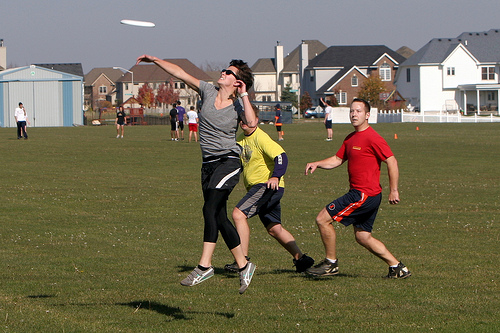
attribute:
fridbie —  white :
[118, 18, 155, 28]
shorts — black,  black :
[324, 186, 383, 233]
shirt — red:
[334, 127, 393, 197]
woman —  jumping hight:
[131, 49, 281, 294]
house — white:
[375, 43, 466, 117]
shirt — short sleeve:
[337, 129, 391, 201]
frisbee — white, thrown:
[120, 17, 155, 29]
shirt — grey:
[197, 80, 246, 157]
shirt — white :
[14, 107, 25, 121]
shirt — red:
[337, 124, 405, 204]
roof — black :
[404, 30, 482, 61]